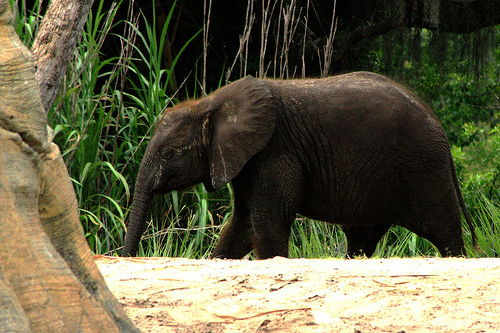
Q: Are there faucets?
A: No, there are no faucets.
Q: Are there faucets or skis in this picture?
A: No, there are no faucets or skis.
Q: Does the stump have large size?
A: Yes, the stump is large.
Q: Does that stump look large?
A: Yes, the stump is large.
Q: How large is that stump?
A: The stump is large.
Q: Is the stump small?
A: No, the stump is large.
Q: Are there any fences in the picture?
A: No, there are no fences.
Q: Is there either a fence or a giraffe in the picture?
A: No, there are no fences or giraffes.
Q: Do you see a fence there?
A: No, there are no fences.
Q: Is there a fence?
A: No, there are no fences.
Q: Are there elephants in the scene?
A: Yes, there is an elephant.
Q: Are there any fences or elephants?
A: Yes, there is an elephant.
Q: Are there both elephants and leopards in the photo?
A: No, there is an elephant but no leopards.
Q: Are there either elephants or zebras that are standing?
A: Yes, the elephant is standing.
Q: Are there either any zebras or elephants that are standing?
A: Yes, the elephant is standing.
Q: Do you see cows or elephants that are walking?
A: Yes, the elephant is walking.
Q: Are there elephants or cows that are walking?
A: Yes, the elephant is walking.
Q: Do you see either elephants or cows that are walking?
A: Yes, the elephant is walking.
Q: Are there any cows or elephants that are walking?
A: Yes, the elephant is walking.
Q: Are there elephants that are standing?
A: Yes, there is an elephant that is standing.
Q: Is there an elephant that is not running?
A: Yes, there is an elephant that is standing.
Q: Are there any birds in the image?
A: No, there are no birds.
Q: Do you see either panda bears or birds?
A: No, there are no birds or panda bears.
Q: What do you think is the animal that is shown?
A: The animal is an elephant.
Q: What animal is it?
A: The animal is an elephant.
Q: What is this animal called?
A: This is an elephant.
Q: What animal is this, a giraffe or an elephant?
A: This is an elephant.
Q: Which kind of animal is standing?
A: The animal is an elephant.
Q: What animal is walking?
A: The animal is an elephant.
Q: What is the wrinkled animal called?
A: The animal is an elephant.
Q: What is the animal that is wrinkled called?
A: The animal is an elephant.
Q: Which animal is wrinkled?
A: The animal is an elephant.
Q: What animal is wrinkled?
A: The animal is an elephant.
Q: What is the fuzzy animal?
A: The animal is an elephant.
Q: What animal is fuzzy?
A: The animal is an elephant.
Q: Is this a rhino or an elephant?
A: This is an elephant.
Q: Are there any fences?
A: No, there are no fences.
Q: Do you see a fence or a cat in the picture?
A: No, there are no fences or cats.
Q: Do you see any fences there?
A: No, there are no fences.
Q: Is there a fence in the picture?
A: No, there are no fences.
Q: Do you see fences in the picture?
A: No, there are no fences.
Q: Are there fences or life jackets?
A: No, there are no fences or life jackets.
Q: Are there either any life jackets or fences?
A: No, there are no fences or life jackets.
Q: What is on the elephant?
A: The trunk is on the elephant.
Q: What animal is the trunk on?
A: The trunk is on the elephant.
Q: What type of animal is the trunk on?
A: The trunk is on the elephant.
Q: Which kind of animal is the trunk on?
A: The trunk is on the elephant.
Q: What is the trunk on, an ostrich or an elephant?
A: The trunk is on an elephant.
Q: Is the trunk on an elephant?
A: Yes, the trunk is on an elephant.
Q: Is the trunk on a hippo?
A: No, the trunk is on an elephant.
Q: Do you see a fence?
A: No, there are no fences.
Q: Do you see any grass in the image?
A: Yes, there is grass.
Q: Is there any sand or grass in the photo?
A: Yes, there is grass.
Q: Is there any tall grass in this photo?
A: Yes, there is tall grass.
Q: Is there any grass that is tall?
A: Yes, there is grass that is tall.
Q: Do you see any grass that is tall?
A: Yes, there is grass that is tall.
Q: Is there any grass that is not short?
A: Yes, there is tall grass.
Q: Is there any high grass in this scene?
A: Yes, there is high grass.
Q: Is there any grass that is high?
A: Yes, there is grass that is high.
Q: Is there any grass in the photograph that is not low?
A: Yes, there is high grass.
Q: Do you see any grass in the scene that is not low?
A: Yes, there is high grass.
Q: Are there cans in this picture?
A: No, there are no cans.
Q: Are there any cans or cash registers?
A: No, there are no cans or cash registers.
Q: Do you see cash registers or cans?
A: No, there are no cans or cash registers.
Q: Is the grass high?
A: Yes, the grass is high.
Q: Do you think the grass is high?
A: Yes, the grass is high.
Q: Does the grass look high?
A: Yes, the grass is high.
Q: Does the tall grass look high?
A: Yes, the grass is high.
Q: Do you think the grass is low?
A: No, the grass is high.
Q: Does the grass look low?
A: No, the grass is high.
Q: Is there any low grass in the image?
A: No, there is grass but it is high.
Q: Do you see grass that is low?
A: No, there is grass but it is high.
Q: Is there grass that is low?
A: No, there is grass but it is high.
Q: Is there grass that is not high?
A: No, there is grass but it is high.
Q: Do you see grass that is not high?
A: No, there is grass but it is high.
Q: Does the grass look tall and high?
A: Yes, the grass is tall and high.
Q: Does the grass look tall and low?
A: No, the grass is tall but high.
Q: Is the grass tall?
A: Yes, the grass is tall.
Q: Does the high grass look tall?
A: Yes, the grass is tall.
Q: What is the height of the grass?
A: The grass is tall.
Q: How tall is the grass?
A: The grass is tall.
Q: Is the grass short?
A: No, the grass is tall.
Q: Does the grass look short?
A: No, the grass is tall.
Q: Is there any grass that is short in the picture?
A: No, there is grass but it is tall.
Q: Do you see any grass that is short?
A: No, there is grass but it is tall.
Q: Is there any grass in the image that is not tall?
A: No, there is grass but it is tall.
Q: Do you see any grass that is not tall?
A: No, there is grass but it is tall.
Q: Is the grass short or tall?
A: The grass is tall.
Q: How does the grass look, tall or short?
A: The grass is tall.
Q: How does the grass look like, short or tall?
A: The grass is tall.